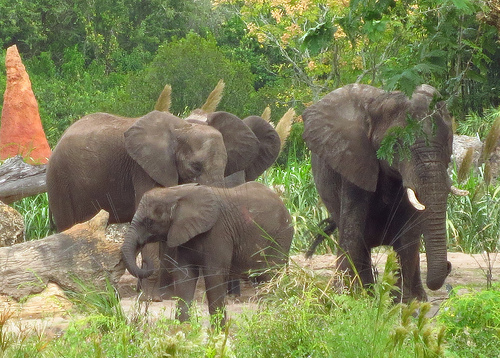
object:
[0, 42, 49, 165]
cone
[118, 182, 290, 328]
baby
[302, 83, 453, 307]
elephant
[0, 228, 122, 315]
log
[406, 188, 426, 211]
tusk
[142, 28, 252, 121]
tree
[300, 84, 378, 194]
ear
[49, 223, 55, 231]
tuft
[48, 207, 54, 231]
tail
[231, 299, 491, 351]
grass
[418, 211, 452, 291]
trunk